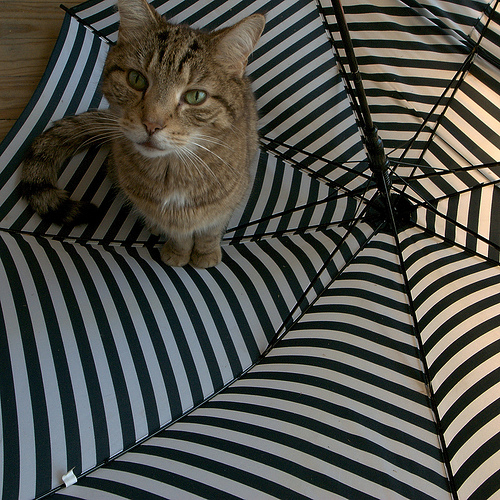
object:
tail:
[20, 107, 117, 228]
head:
[96, 0, 266, 161]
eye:
[181, 90, 209, 107]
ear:
[110, 0, 163, 38]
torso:
[112, 81, 258, 227]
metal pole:
[313, 5, 406, 246]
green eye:
[185, 89, 208, 106]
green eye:
[128, 69, 148, 92]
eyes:
[124, 67, 209, 108]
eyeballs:
[127, 66, 210, 107]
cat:
[19, 0, 266, 271]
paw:
[160, 232, 191, 267]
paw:
[192, 229, 222, 269]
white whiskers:
[54, 101, 235, 187]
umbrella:
[3, 1, 499, 498]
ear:
[203, 12, 271, 84]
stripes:
[132, 158, 216, 220]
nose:
[139, 112, 171, 141]